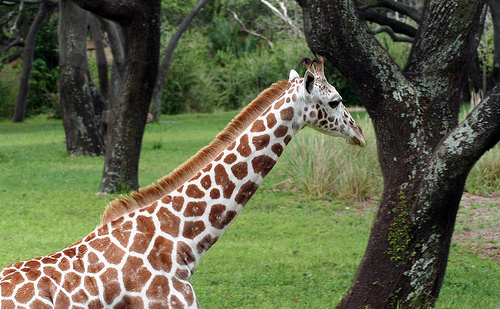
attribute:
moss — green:
[381, 187, 427, 275]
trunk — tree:
[326, 170, 461, 301]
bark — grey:
[441, 116, 482, 162]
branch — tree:
[440, 83, 498, 178]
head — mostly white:
[285, 64, 367, 149]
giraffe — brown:
[4, 54, 371, 304]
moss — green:
[352, 59, 446, 288]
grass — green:
[5, 172, 76, 214]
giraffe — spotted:
[87, 113, 382, 276]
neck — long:
[147, 93, 314, 251]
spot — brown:
[12, 279, 40, 307]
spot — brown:
[63, 270, 108, 306]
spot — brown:
[83, 253, 118, 278]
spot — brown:
[123, 236, 164, 298]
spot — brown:
[123, 226, 203, 271]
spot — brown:
[77, 232, 143, 276]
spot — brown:
[94, 219, 181, 272]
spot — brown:
[173, 213, 249, 251]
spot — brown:
[174, 191, 241, 230]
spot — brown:
[180, 178, 223, 220]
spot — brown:
[281, 109, 321, 126]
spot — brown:
[228, 122, 280, 154]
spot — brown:
[257, 143, 280, 177]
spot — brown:
[207, 132, 270, 187]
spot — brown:
[171, 170, 203, 199]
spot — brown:
[167, 180, 206, 206]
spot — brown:
[175, 182, 216, 249]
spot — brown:
[146, 209, 176, 244]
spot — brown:
[144, 232, 178, 273]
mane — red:
[88, 76, 289, 223]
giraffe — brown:
[226, 156, 251, 179]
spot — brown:
[148, 233, 175, 273]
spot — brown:
[119, 253, 151, 289]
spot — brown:
[233, 174, 258, 212]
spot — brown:
[61, 269, 84, 290]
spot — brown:
[70, 253, 88, 271]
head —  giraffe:
[274, 50, 372, 147]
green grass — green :
[12, 74, 397, 296]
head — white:
[286, 60, 363, 148]